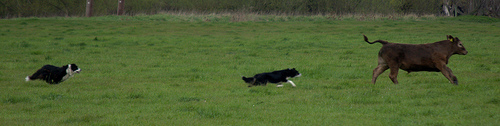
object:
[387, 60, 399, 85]
leg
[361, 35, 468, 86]
cow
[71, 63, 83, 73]
face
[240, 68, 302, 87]
animals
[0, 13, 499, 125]
field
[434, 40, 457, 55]
neck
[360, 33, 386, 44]
tail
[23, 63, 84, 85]
dog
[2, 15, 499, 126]
ground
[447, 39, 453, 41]
tag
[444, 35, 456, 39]
ear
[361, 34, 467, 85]
animal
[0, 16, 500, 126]
grass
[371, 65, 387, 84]
leg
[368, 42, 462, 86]
body